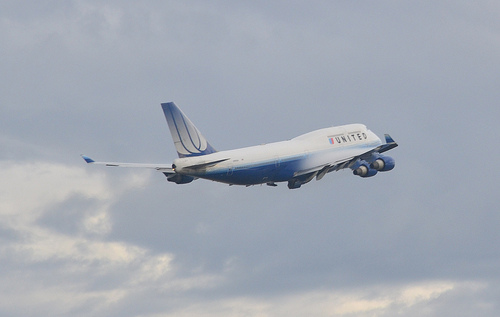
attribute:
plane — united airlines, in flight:
[69, 105, 422, 228]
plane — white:
[59, 82, 419, 211]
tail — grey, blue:
[59, 155, 174, 202]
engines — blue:
[342, 142, 405, 208]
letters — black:
[326, 129, 406, 155]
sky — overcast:
[224, 48, 427, 100]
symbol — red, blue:
[312, 130, 342, 157]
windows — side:
[318, 130, 391, 160]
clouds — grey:
[20, 183, 211, 295]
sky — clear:
[310, 49, 420, 113]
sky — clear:
[172, 34, 297, 116]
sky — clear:
[386, 206, 482, 291]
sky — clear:
[319, 46, 437, 122]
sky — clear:
[281, 33, 454, 82]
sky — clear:
[374, 219, 456, 244]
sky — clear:
[25, 85, 70, 127]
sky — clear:
[175, 208, 237, 229]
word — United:
[327, 129, 375, 146]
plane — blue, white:
[84, 100, 402, 206]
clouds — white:
[12, 156, 64, 246]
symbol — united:
[322, 134, 338, 152]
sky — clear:
[8, 4, 498, 307]